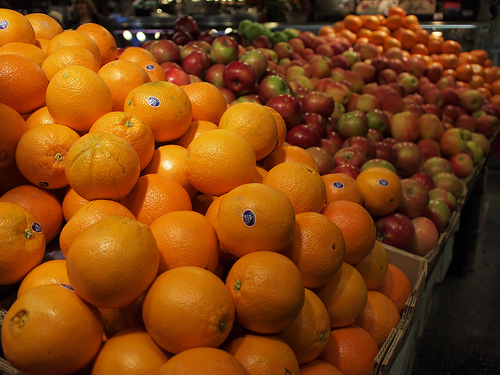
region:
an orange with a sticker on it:
[125, 77, 192, 142]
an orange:
[185, 125, 255, 195]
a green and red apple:
[210, 32, 240, 62]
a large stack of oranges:
[0, 12, 382, 367]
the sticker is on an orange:
[240, 205, 256, 228]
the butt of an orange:
[10, 305, 28, 325]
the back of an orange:
[65, 130, 140, 200]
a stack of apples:
[270, 52, 325, 108]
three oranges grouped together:
[65, 207, 227, 349]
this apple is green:
[245, 21, 265, 40]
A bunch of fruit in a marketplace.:
[2, 7, 493, 367]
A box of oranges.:
[1, 5, 421, 372]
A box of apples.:
[148, 32, 481, 253]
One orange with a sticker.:
[210, 173, 302, 260]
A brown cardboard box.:
[368, 235, 437, 369]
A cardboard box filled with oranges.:
[1, 9, 432, 366]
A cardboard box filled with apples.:
[205, 32, 479, 286]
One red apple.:
[220, 58, 257, 95]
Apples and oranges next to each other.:
[0, 5, 489, 371]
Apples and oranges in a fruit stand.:
[4, 5, 487, 373]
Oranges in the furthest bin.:
[318, 6, 499, 104]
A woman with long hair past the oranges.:
[69, 2, 107, 29]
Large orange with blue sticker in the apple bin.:
[358, 167, 401, 212]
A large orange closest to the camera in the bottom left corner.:
[1, 281, 104, 373]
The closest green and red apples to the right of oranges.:
[134, 35, 488, 260]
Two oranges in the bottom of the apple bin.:
[320, 167, 402, 215]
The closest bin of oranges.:
[1, 8, 411, 373]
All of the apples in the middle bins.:
[145, 13, 499, 253]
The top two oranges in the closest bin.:
[1, 7, 63, 45]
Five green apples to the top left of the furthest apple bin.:
[237, 20, 297, 42]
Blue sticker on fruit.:
[234, 202, 256, 228]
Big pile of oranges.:
[19, 14, 219, 277]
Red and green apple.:
[342, 109, 384, 151]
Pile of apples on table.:
[273, 82, 447, 160]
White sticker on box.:
[397, 335, 418, 363]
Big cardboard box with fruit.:
[390, 248, 459, 363]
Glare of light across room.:
[118, 20, 149, 41]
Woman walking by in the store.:
[58, 2, 116, 24]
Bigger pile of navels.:
[362, 23, 479, 82]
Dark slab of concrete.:
[454, 271, 489, 328]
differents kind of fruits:
[0, 2, 489, 369]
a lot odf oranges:
[0, 19, 389, 372]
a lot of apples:
[286, 41, 483, 127]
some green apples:
[240, 17, 290, 39]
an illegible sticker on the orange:
[242, 210, 256, 227]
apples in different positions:
[216, 49, 426, 101]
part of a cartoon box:
[386, 257, 421, 364]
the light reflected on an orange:
[157, 159, 172, 170]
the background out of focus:
[68, 2, 344, 23]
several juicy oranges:
[12, 146, 299, 331]